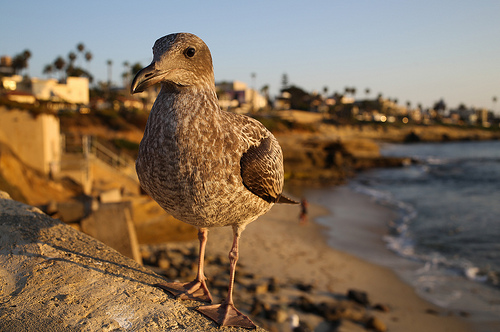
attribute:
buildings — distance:
[270, 62, 498, 147]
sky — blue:
[0, 0, 498, 116]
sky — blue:
[5, 4, 499, 109]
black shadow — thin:
[0, 211, 148, 283]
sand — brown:
[269, 214, 490, 329]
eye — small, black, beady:
[175, 42, 205, 62]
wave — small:
[391, 225, 470, 292]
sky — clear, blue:
[245, 5, 498, 85]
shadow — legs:
[54, 231, 132, 296]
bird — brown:
[109, 10, 238, 115]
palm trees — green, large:
[41, 42, 93, 75]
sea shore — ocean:
[334, 117, 496, 312]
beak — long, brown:
[120, 67, 171, 92]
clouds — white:
[289, 15, 432, 104]